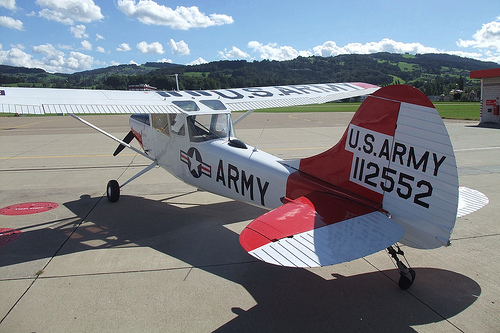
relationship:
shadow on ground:
[2, 189, 480, 330] [0, 116, 496, 330]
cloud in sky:
[23, 0, 105, 26] [3, 2, 497, 72]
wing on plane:
[0, 82, 381, 122] [2, 80, 491, 298]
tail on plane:
[277, 85, 460, 246] [2, 80, 491, 298]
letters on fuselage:
[214, 156, 270, 210] [134, 118, 301, 214]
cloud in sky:
[38, 0, 236, 34] [3, 2, 497, 72]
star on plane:
[185, 149, 199, 178] [2, 80, 491, 298]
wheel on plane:
[107, 180, 120, 203] [2, 80, 491, 298]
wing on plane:
[0, 82, 381, 114] [2, 80, 491, 298]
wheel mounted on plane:
[394, 272, 413, 291] [2, 80, 491, 298]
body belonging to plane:
[141, 125, 298, 211] [2, 80, 491, 298]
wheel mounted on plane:
[399, 270, 416, 290] [1, 69, 484, 289]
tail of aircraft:
[309, 79, 494, 275] [48, 35, 498, 330]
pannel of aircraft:
[237, 190, 403, 285] [48, 43, 494, 280]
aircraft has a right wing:
[94, 85, 464, 285] [213, 73, 365, 110]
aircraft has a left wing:
[94, 85, 464, 285] [2, 81, 182, 121]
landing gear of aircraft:
[102, 154, 157, 199] [4, 77, 488, 291]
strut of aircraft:
[75, 118, 153, 163] [4, 77, 488, 291]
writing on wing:
[344, 128, 450, 208] [282, 86, 459, 253]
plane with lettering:
[69, 67, 453, 307] [334, 110, 443, 210]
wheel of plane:
[106, 175, 119, 201] [2, 80, 491, 298]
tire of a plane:
[105, 180, 120, 202] [2, 80, 491, 298]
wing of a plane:
[0, 82, 381, 114] [2, 80, 491, 298]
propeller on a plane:
[113, 130, 133, 155] [2, 80, 491, 298]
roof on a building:
[468, 63, 498, 76] [470, 66, 499, 121]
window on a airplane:
[185, 112, 234, 140] [1, 74, 488, 287]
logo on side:
[179, 146, 211, 178] [127, 115, 313, 207]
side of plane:
[127, 115, 313, 207] [2, 80, 491, 298]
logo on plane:
[179, 146, 211, 178] [2, 80, 491, 298]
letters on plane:
[350, 129, 447, 207] [2, 80, 491, 298]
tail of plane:
[277, 85, 460, 246] [2, 80, 491, 298]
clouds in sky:
[1, 1, 499, 74] [3, 2, 497, 72]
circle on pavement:
[1, 200, 59, 215] [6, 110, 492, 324]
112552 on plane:
[352, 157, 432, 209] [2, 80, 491, 298]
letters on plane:
[348, 124, 377, 155] [2, 80, 491, 298]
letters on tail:
[348, 124, 377, 155] [277, 85, 460, 246]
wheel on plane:
[399, 270, 416, 290] [2, 80, 491, 298]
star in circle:
[189, 150, 202, 177] [184, 144, 203, 178]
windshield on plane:
[182, 113, 231, 141] [2, 80, 491, 298]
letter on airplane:
[348, 129, 360, 147] [1, 74, 488, 287]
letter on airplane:
[361, 133, 375, 152] [1, 74, 488, 287]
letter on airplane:
[379, 137, 391, 159] [1, 74, 488, 287]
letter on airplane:
[392, 142, 408, 163] [1, 74, 488, 287]